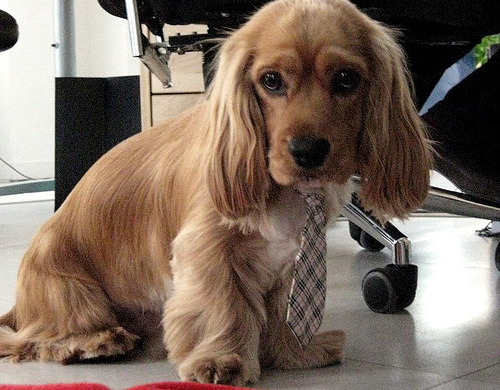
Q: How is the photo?
A: Clear.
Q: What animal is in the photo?
A: Dog.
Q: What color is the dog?
A: Brown.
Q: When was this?
A: Daytime.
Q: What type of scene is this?
A: Indoor.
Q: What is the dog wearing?
A: A tie.